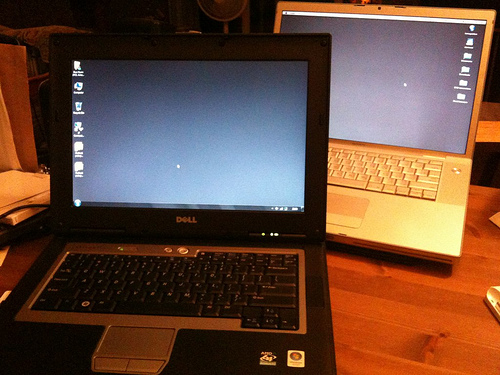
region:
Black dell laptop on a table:
[0, 35, 339, 372]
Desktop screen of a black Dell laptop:
[52, 35, 320, 229]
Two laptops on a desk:
[4, 4, 491, 374]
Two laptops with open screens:
[2, 0, 495, 372]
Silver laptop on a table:
[267, 3, 496, 269]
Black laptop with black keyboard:
[4, 35, 335, 368]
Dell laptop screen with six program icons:
[51, 39, 323, 226]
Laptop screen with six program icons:
[267, 0, 495, 157]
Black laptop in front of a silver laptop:
[2, 2, 493, 369]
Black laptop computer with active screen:
[4, 33, 336, 371]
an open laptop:
[2, 25, 336, 372]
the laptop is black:
[1, 34, 335, 374]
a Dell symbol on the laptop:
[172, 212, 202, 231]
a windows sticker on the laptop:
[283, 347, 308, 367]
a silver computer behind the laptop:
[257, 0, 496, 274]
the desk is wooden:
[3, 140, 493, 373]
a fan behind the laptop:
[197, 2, 262, 37]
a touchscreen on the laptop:
[95, 322, 177, 363]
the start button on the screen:
[72, 194, 85, 206]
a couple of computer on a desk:
[16, 0, 493, 372]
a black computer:
[9, 33, 328, 371]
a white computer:
[322, 6, 493, 241]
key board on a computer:
[45, 248, 298, 325]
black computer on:
[11, 33, 332, 371]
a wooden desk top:
[347, 270, 497, 370]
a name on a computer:
[170, 211, 199, 226]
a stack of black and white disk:
[0, 164, 50, 254]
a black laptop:
[0, 33, 332, 373]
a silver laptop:
[273, 0, 496, 262]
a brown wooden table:
[1, 183, 496, 373]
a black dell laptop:
[2, 33, 338, 374]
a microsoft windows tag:
[283, 349, 305, 369]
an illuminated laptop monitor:
[48, 35, 331, 235]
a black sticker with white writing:
[256, 348, 277, 368]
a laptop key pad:
[18, 241, 309, 332]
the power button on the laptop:
[174, 245, 189, 256]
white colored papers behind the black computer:
[1, 43, 47, 215]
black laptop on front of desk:
[3, 28, 336, 368]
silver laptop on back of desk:
[268, 2, 498, 273]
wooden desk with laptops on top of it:
[331, 185, 497, 373]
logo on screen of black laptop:
[72, 59, 83, 78]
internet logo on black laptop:
[71, 77, 84, 97]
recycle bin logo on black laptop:
[71, 98, 88, 118]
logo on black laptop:
[71, 119, 85, 136]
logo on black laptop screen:
[70, 141, 85, 160]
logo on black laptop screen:
[71, 159, 86, 179]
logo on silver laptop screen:
[446, 87, 471, 107]